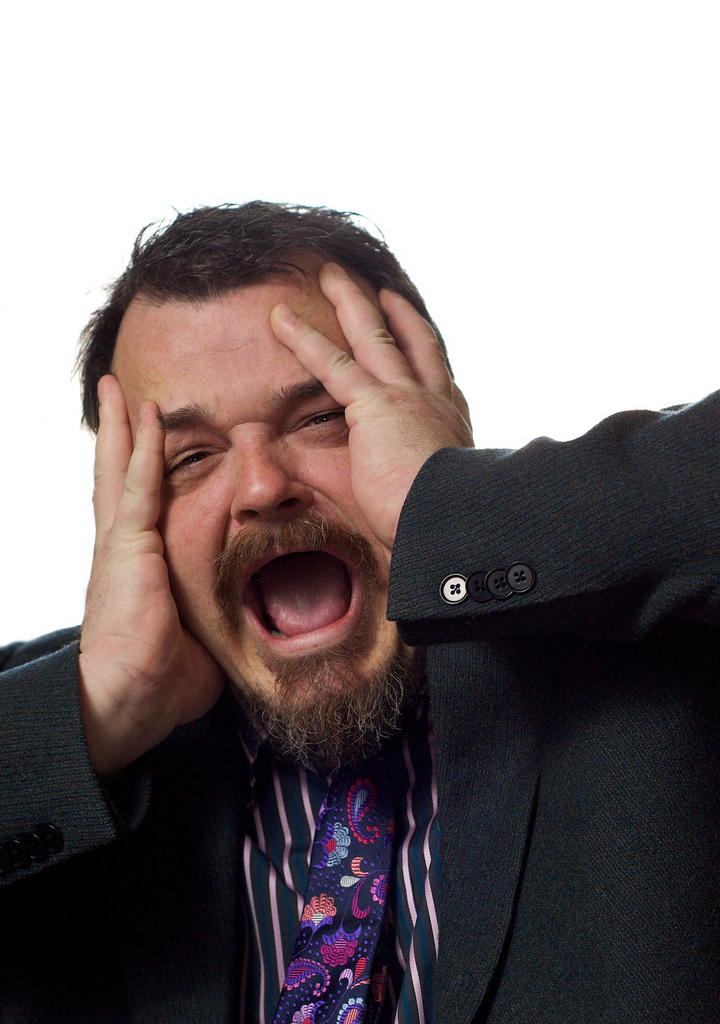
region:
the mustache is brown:
[207, 508, 379, 632]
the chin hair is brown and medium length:
[240, 590, 410, 774]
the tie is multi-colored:
[270, 752, 400, 1022]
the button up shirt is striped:
[239, 706, 444, 1022]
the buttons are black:
[439, 559, 540, 601]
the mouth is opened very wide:
[237, 537, 365, 661]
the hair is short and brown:
[74, 198, 454, 437]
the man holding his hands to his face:
[5, 202, 716, 1022]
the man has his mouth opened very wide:
[0, 198, 719, 1018]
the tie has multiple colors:
[274, 769, 396, 1022]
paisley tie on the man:
[277, 755, 423, 1022]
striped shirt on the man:
[222, 698, 432, 1020]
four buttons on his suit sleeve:
[428, 559, 547, 604]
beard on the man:
[236, 637, 423, 774]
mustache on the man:
[208, 512, 395, 595]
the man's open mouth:
[215, 514, 370, 670]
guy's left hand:
[251, 254, 455, 554]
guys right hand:
[60, 340, 238, 713]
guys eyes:
[141, 379, 389, 491]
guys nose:
[214, 420, 308, 546]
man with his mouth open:
[7, 199, 713, 1021]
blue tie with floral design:
[275, 763, 402, 1022]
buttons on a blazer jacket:
[437, 558, 547, 606]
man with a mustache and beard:
[3, 203, 717, 1022]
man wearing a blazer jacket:
[12, 199, 713, 1021]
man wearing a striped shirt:
[1, 204, 718, 1022]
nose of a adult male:
[213, 464, 320, 522]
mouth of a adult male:
[236, 535, 367, 660]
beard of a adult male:
[254, 658, 411, 773]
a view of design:
[299, 875, 359, 973]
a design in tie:
[333, 882, 394, 988]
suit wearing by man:
[116, 819, 670, 985]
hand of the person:
[315, 300, 442, 538]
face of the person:
[66, 296, 595, 892]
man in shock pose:
[69, 235, 579, 728]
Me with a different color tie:
[252, 761, 425, 994]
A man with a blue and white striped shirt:
[384, 744, 474, 965]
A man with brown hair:
[71, 208, 454, 336]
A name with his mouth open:
[91, 404, 459, 824]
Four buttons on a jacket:
[407, 474, 656, 633]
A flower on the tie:
[299, 888, 347, 965]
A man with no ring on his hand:
[291, 304, 500, 418]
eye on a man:
[153, 424, 211, 477]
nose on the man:
[215, 452, 317, 545]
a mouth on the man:
[217, 535, 407, 648]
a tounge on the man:
[282, 550, 420, 692]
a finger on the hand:
[248, 290, 372, 423]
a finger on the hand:
[130, 426, 195, 573]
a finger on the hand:
[93, 378, 124, 524]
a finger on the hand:
[330, 239, 384, 377]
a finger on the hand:
[402, 277, 453, 446]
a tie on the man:
[273, 781, 443, 966]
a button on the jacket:
[409, 569, 460, 618]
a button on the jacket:
[456, 569, 480, 616]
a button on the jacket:
[485, 552, 507, 607]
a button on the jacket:
[524, 554, 544, 597]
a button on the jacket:
[30, 811, 75, 864]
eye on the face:
[283, 375, 328, 449]